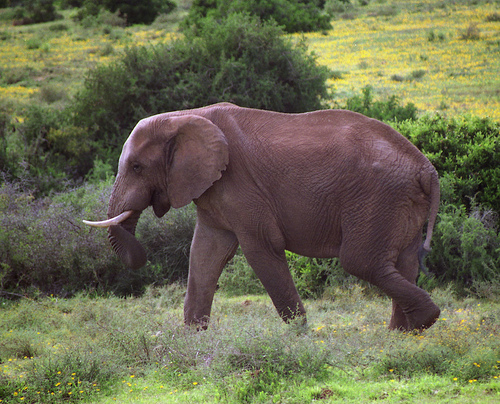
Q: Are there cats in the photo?
A: No, there are no cats.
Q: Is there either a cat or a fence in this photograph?
A: No, there are no cats or fences.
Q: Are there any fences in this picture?
A: No, there are no fences.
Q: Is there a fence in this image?
A: No, there are no fences.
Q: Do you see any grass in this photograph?
A: Yes, there is grass.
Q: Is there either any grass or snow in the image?
A: Yes, there is grass.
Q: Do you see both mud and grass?
A: No, there is grass but no mud.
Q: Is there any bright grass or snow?
A: Yes, there is bright grass.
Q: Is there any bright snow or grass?
A: Yes, there is bright grass.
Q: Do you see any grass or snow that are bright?
A: Yes, the grass is bright.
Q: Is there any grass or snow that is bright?
A: Yes, the grass is bright.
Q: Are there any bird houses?
A: No, there are no bird houses.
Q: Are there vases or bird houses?
A: No, there are no bird houses or vases.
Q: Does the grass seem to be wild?
A: Yes, the grass is wild.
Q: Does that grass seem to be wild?
A: Yes, the grass is wild.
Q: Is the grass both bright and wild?
A: Yes, the grass is bright and wild.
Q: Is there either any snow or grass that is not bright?
A: No, there is grass but it is bright.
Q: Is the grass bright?
A: Yes, the grass is bright.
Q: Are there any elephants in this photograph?
A: Yes, there is an elephant.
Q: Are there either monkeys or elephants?
A: Yes, there is an elephant.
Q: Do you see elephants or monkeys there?
A: Yes, there is an elephant.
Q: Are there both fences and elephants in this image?
A: No, there is an elephant but no fences.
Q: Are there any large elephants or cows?
A: Yes, there is a large elephant.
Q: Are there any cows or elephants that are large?
A: Yes, the elephant is large.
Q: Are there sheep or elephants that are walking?
A: Yes, the elephant is walking.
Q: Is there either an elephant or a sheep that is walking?
A: Yes, the elephant is walking.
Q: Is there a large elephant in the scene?
A: Yes, there is a large elephant.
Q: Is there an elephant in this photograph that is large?
A: Yes, there is an elephant that is large.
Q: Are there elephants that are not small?
A: Yes, there is a large elephant.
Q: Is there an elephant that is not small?
A: Yes, there is a large elephant.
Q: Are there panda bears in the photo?
A: No, there are no panda bears.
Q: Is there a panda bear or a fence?
A: No, there are no panda bears or fences.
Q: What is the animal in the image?
A: The animal is an elephant.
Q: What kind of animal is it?
A: The animal is an elephant.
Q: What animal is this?
A: This is an elephant.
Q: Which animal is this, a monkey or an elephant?
A: This is an elephant.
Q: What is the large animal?
A: The animal is an elephant.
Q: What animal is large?
A: The animal is an elephant.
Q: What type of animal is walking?
A: The animal is an elephant.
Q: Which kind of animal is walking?
A: The animal is an elephant.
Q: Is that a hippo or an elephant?
A: That is an elephant.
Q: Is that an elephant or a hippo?
A: That is an elephant.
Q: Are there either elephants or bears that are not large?
A: No, there is an elephant but it is large.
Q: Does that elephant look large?
A: Yes, the elephant is large.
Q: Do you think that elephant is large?
A: Yes, the elephant is large.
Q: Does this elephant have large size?
A: Yes, the elephant is large.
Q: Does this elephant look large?
A: Yes, the elephant is large.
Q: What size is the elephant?
A: The elephant is large.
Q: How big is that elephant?
A: The elephant is large.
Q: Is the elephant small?
A: No, the elephant is large.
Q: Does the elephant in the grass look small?
A: No, the elephant is large.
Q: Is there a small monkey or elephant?
A: No, there is an elephant but it is large.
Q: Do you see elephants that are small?
A: No, there is an elephant but it is large.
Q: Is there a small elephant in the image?
A: No, there is an elephant but it is large.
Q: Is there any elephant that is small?
A: No, there is an elephant but it is large.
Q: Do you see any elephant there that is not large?
A: No, there is an elephant but it is large.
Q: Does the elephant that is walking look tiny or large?
A: The elephant is large.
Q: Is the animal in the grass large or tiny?
A: The elephant is large.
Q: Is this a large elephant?
A: Yes, this is a large elephant.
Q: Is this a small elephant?
A: No, this is a large elephant.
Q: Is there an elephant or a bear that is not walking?
A: No, there is an elephant but it is walking.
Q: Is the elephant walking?
A: Yes, the elephant is walking.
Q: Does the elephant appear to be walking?
A: Yes, the elephant is walking.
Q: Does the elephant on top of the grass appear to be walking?
A: Yes, the elephant is walking.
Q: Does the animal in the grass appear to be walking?
A: Yes, the elephant is walking.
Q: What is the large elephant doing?
A: The elephant is walking.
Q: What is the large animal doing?
A: The elephant is walking.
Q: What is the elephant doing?
A: The elephant is walking.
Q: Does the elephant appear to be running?
A: No, the elephant is walking.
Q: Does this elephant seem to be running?
A: No, the elephant is walking.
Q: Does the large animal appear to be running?
A: No, the elephant is walking.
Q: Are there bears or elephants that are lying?
A: No, there is an elephant but it is walking.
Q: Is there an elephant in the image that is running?
A: No, there is an elephant but it is walking.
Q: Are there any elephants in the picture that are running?
A: No, there is an elephant but it is walking.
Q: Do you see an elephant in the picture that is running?
A: No, there is an elephant but it is walking.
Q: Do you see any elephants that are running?
A: No, there is an elephant but it is walking.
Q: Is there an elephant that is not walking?
A: No, there is an elephant but it is walking.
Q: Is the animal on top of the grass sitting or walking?
A: The elephant is walking.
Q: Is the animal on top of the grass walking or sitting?
A: The elephant is walking.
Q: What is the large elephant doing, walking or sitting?
A: The elephant is walking.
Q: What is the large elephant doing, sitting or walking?
A: The elephant is walking.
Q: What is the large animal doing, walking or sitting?
A: The elephant is walking.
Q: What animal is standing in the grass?
A: The elephant is standing in the grass.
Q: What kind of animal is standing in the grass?
A: The animal is an elephant.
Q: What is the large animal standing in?
A: The elephant is standing in the grass.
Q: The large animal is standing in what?
A: The elephant is standing in the grass.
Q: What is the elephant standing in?
A: The elephant is standing in the grass.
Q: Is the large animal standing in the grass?
A: Yes, the elephant is standing in the grass.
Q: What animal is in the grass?
A: The animal is an elephant.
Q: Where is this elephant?
A: The elephant is in the grass.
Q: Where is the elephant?
A: The elephant is in the grass.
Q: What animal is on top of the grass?
A: The elephant is on top of the grass.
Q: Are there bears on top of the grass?
A: No, there is an elephant on top of the grass.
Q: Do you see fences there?
A: No, there are no fences.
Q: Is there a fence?
A: No, there are no fences.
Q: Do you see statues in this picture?
A: No, there are no statues.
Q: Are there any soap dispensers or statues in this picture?
A: No, there are no statues or soap dispensers.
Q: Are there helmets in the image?
A: No, there are no helmets.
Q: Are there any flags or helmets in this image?
A: No, there are no helmets or flags.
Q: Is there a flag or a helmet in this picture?
A: No, there are no helmets or flags.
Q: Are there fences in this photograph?
A: No, there are no fences.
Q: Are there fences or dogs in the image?
A: No, there are no fences or dogs.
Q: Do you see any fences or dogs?
A: No, there are no fences or dogs.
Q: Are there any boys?
A: No, there are no boys.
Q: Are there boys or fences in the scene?
A: No, there are no boys or fences.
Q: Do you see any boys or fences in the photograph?
A: No, there are no boys or fences.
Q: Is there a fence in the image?
A: No, there are no fences.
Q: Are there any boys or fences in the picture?
A: No, there are no fences or boys.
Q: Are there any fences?
A: No, there are no fences.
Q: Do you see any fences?
A: No, there are no fences.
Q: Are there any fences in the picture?
A: No, there are no fences.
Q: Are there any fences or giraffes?
A: No, there are no fences or giraffes.